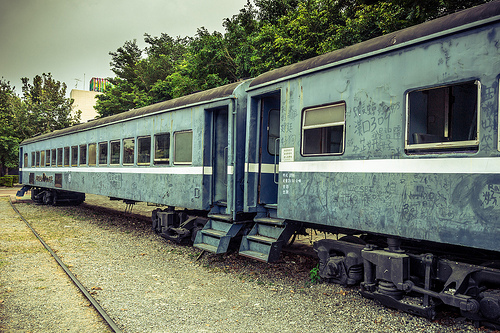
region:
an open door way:
[231, 81, 296, 220]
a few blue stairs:
[189, 190, 304, 281]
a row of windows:
[21, 139, 163, 171]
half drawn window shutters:
[293, 100, 355, 157]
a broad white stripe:
[43, 156, 202, 180]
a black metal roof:
[13, 90, 253, 135]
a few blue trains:
[8, 66, 496, 233]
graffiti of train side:
[317, 175, 498, 235]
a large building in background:
[58, 61, 120, 122]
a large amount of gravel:
[87, 232, 166, 329]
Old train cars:
[15, 18, 499, 300]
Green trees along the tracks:
[82, 2, 464, 122]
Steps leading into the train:
[191, 192, 293, 282]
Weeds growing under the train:
[307, 262, 327, 294]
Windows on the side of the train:
[22, 120, 202, 173]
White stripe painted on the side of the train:
[274, 148, 499, 188]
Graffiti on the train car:
[348, 93, 405, 155]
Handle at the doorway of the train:
[265, 130, 284, 187]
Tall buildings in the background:
[65, 62, 125, 127]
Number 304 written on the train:
[361, 106, 396, 139]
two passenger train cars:
[25, 41, 495, 286]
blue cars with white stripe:
[19, 77, 499, 267]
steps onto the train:
[188, 183, 284, 267]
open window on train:
[285, 90, 370, 170]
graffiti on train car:
[347, 88, 402, 173]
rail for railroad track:
[8, 193, 127, 328]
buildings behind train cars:
[64, 64, 123, 116]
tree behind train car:
[7, 75, 81, 185]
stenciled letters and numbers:
[277, 165, 306, 216]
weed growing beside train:
[296, 256, 329, 293]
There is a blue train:
[15, 9, 475, 281]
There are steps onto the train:
[186, 205, 236, 268]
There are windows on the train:
[273, 85, 350, 177]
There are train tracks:
[32, 230, 112, 307]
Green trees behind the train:
[79, 25, 264, 127]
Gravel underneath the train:
[137, 262, 304, 327]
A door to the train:
[231, 73, 288, 228]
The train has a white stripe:
[250, 147, 460, 193]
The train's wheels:
[274, 246, 479, 315]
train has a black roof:
[14, 77, 242, 148]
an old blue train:
[12, 6, 492, 310]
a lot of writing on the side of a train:
[331, 84, 488, 241]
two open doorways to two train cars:
[189, 82, 294, 217]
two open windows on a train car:
[287, 65, 499, 168]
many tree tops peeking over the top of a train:
[93, 2, 463, 129]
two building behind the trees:
[51, 70, 136, 132]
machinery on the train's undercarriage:
[293, 220, 498, 315]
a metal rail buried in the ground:
[6, 192, 131, 330]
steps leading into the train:
[188, 184, 299, 270]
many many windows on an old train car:
[21, 115, 203, 173]